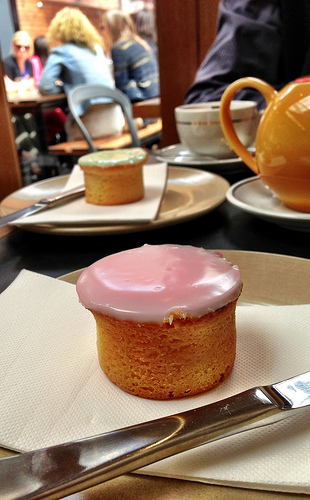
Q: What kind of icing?
A: Pink.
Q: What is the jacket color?
A: Blue.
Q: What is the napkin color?
A: White.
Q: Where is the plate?
A: On the napkin.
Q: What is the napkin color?
A: White.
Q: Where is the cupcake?
A: Napkin.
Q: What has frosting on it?
A: The cupcake.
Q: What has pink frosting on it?
A: A cupcake.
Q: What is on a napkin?
A: The cupcake.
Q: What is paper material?
A: The napkin.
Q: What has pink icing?
A: A cupcake.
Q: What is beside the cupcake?
A: A silver knife.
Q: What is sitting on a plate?
A: A cupcake.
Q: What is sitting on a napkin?
A: A cupcake.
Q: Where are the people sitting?
A: A table.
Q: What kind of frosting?
A: Pink.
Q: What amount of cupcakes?
A: Two.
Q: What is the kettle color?
A: Tan.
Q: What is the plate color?
A: Brown.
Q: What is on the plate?
A: Cupcake.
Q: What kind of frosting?
A: Pink.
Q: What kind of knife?
A: Butterknife.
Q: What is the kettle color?
A: Orange.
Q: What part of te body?
A: Arm.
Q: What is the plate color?
A: Tan.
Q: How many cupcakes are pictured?
A: 2.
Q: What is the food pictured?
A: Cupcake.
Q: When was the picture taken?
A: Afternoon.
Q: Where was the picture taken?
A: Restaurant.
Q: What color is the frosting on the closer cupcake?
A: Pink.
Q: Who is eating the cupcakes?
A: Nobody.